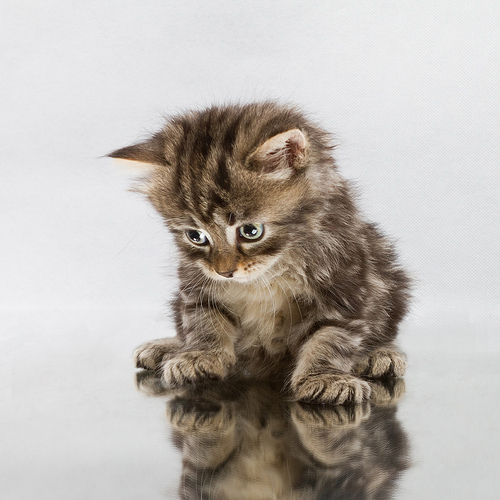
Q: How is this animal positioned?
A: Sitting.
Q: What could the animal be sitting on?
A: Mirror.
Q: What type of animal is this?
A: Kitten.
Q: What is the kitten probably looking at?
A: Itself.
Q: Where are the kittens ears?
A: On its head.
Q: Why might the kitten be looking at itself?
A: Curiosity.